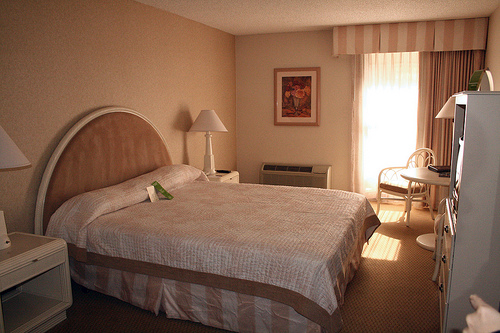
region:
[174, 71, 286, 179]
a lamp near a bed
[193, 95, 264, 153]
a white lamp in a room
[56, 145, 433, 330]
a bed in a room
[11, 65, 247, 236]
a headboard to a bed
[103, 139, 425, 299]
a blanket on a bed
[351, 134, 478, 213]
a chair in a room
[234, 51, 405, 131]
a picture on the wall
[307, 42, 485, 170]
curtains on a window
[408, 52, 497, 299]
a dresser in a room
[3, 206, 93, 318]
a table on the side of the bed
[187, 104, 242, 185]
Lamp on an end table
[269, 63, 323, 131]
Painting hanging on the wall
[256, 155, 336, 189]
A radiator against the wall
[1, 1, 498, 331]
A clean and tidy bedroom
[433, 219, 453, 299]
Three handles of drawers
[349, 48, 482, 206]
Curtains covering a window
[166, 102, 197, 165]
Shadow on the wall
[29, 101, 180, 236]
The bed's headboard is round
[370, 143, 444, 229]
A chair next to the window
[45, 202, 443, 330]
Carpet on the floor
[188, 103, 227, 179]
Lamp on the nightstand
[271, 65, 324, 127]
Painting on the wall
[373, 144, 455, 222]
White chair and table by the window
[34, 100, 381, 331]
Neaty made bed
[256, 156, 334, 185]
Heat and air unit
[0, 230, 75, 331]
Night stand to left of bed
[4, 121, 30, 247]
Lamp on top of night stand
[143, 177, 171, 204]
Instruction cards on the bed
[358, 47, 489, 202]
Sliding glass door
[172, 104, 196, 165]
Shadow of lamp on wall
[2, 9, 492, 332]
a hotel room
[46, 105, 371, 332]
a bed in a hotel room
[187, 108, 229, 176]
a lamp on a stand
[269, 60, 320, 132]
a picture on the wall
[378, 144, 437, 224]
a chair by a table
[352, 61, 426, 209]
sun shining through a window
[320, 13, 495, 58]
a valance hanging at a window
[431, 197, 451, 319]
drawers in a cupboard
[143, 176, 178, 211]
flyers on a bed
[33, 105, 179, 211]
headboard on a bed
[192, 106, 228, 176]
White bedside table lamp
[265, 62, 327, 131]
Picture frame on wall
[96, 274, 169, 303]
Part of bed dust ruffle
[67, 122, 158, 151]
Part of bed headboard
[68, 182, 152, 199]
Part of large white pillow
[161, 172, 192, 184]
Part of large white pillow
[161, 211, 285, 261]
Part of large bed comforter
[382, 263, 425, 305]
Part of floor covering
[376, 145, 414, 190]
Part of bedroom chair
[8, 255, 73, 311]
Part of side table chest